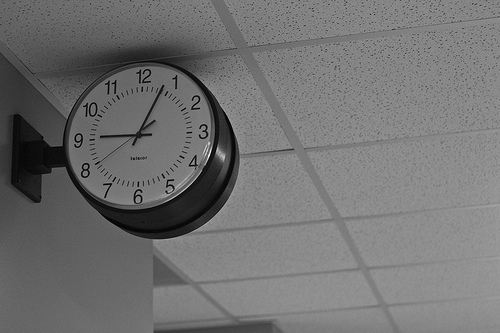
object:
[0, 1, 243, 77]
tile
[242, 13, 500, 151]
tile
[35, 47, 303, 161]
tile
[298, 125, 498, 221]
tile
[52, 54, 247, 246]
clock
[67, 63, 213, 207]
face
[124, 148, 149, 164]
manufacturer print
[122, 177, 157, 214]
number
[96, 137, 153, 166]
second hand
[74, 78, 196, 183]
circle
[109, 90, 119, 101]
lines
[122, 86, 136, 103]
lines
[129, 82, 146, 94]
lines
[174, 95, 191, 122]
lines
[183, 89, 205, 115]
two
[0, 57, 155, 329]
wall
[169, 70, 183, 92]
one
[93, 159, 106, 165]
part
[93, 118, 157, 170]
hand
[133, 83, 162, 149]
hand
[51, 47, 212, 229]
time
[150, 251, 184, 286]
lights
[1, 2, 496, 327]
ceiling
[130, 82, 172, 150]
hand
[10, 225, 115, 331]
wall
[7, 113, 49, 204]
metal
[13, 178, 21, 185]
screw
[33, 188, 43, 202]
screw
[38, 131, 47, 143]
screw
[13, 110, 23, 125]
screw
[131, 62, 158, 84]
12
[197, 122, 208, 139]
number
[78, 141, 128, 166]
hand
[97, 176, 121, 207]
number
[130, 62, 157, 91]
twelve symbol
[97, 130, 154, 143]
hour hand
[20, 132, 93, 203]
support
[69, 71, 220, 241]
number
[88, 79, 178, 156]
hands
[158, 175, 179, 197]
symbol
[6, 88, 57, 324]
wall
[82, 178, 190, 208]
numbers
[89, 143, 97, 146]
markings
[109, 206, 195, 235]
metal